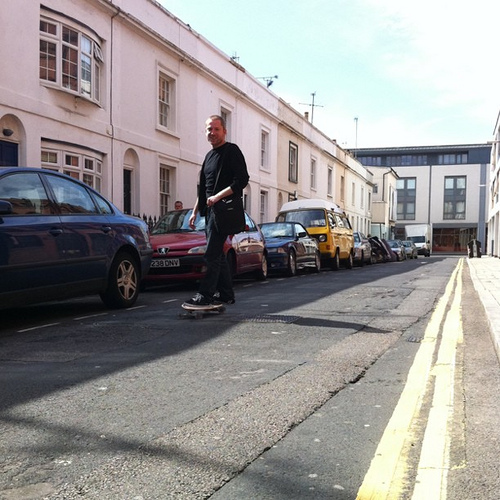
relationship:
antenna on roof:
[297, 89, 328, 135] [201, 83, 359, 226]